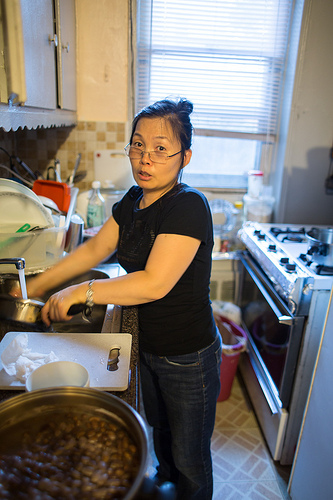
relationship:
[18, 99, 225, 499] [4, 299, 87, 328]
woman washing pan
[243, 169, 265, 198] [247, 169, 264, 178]
bottle has a lid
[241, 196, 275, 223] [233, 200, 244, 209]
bottle has a lid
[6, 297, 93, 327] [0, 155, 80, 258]
pan a cooking utensils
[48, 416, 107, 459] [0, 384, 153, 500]
beans in a pot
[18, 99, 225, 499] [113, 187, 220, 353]
woman wearing shirt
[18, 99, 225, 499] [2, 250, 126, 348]
woman by sink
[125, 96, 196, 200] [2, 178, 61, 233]
woman washing dishes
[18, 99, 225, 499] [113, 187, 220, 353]
woman wearing a shirt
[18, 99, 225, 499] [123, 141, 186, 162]
woman wearing glasses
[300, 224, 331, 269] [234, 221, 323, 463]
pot on stove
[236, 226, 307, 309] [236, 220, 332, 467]
aluminum foil on stove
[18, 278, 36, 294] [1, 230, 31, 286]
water from faucet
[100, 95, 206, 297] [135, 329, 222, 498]
woman wearing jeans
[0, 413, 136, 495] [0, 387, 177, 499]
beans in pot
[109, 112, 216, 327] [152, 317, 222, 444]
woman wearing jeans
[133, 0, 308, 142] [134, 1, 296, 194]
blinds on window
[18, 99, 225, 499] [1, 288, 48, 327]
woman washing pan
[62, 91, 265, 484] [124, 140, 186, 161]
woman wearing glasses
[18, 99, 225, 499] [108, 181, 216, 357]
woman wearing shirt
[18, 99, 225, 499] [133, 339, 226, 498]
woman wearing jeans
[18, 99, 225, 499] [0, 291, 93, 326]
woman washing pot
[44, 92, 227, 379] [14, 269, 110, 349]
woman holding pot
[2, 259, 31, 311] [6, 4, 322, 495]
faucet in kitchen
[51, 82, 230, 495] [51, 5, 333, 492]
woman standing in kitchen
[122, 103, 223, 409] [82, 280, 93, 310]
woman wearing bracelet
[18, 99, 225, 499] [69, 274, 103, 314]
woman wearing bracelet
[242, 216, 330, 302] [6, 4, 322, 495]
stove standing inside kitchen